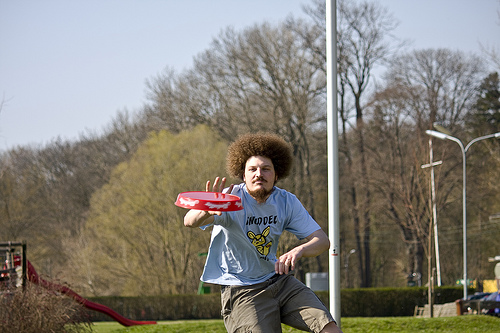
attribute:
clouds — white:
[398, 22, 445, 59]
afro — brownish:
[223, 129, 292, 176]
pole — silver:
[324, 0, 344, 332]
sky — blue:
[0, 2, 226, 133]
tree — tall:
[276, 9, 381, 289]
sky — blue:
[1, 5, 493, 114]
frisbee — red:
[118, 172, 250, 246]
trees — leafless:
[49, 10, 474, 307]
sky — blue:
[27, 14, 262, 120]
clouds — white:
[4, 5, 499, 136]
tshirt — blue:
[196, 182, 323, 284]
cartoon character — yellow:
[243, 222, 273, 258]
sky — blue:
[17, 22, 122, 132]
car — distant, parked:
[473, 289, 498, 315]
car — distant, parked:
[458, 288, 487, 316]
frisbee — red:
[172, 190, 244, 212]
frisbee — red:
[170, 183, 257, 227]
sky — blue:
[1, 0, 499, 152]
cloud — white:
[34, 10, 134, 65]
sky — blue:
[37, 21, 119, 70]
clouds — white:
[70, 18, 150, 98]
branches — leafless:
[356, 37, 378, 93]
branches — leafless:
[298, 24, 325, 70]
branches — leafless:
[337, 0, 362, 61]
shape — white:
[204, 200, 227, 210]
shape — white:
[233, 199, 240, 207]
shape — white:
[176, 194, 197, 209]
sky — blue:
[7, 9, 147, 139]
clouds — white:
[4, 80, 127, 123]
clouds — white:
[10, 86, 120, 139]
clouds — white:
[6, 82, 124, 130]